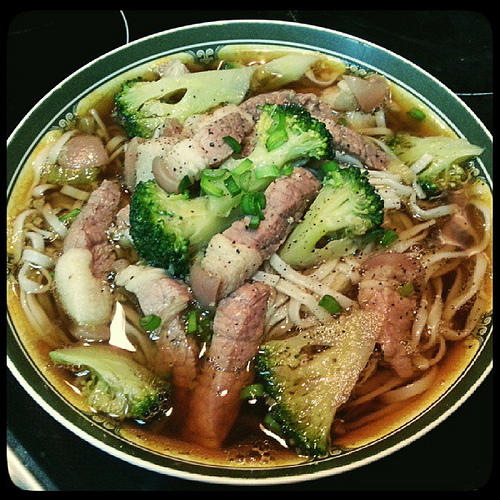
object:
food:
[149, 111, 254, 194]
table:
[0, 0, 500, 500]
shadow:
[3, 440, 39, 491]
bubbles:
[227, 442, 273, 465]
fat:
[201, 233, 262, 303]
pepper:
[207, 139, 216, 149]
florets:
[48, 245, 123, 332]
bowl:
[4, 16, 492, 491]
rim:
[2, 17, 495, 488]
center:
[218, 166, 268, 218]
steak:
[304, 113, 391, 177]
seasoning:
[230, 238, 237, 247]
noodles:
[37, 202, 68, 244]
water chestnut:
[131, 138, 178, 190]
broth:
[5, 42, 495, 472]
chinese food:
[2, 46, 492, 474]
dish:
[6, 20, 496, 488]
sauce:
[5, 43, 493, 479]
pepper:
[161, 333, 173, 344]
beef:
[180, 281, 267, 452]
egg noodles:
[59, 181, 90, 202]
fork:
[5, 445, 43, 491]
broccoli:
[46, 342, 172, 419]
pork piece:
[238, 188, 267, 233]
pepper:
[128, 275, 135, 282]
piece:
[314, 294, 345, 319]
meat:
[352, 249, 426, 379]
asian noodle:
[267, 252, 354, 311]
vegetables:
[124, 173, 227, 269]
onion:
[337, 68, 390, 111]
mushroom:
[57, 127, 111, 179]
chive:
[402, 104, 423, 127]